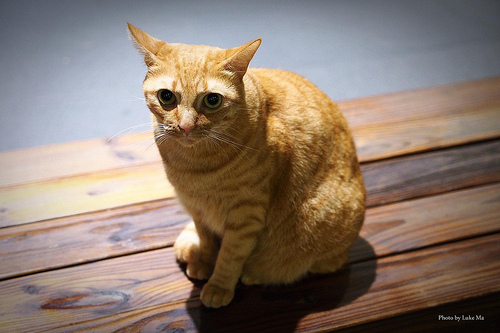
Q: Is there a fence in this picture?
A: No, there are no fences.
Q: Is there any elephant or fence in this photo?
A: No, there are no fences or elephants.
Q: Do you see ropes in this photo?
A: No, there are no ropes.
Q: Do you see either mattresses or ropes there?
A: No, there are no ropes or mattresses.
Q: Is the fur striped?
A: Yes, the fur is striped.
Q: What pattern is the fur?
A: The fur is striped.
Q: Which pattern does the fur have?
A: The fur has striped pattern.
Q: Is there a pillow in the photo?
A: No, there are no pillows.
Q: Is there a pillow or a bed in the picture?
A: No, there are no pillows or beds.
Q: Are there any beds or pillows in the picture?
A: No, there are no pillows or beds.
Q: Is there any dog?
A: No, there are no dogs.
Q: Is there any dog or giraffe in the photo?
A: No, there are no dogs or giraffes.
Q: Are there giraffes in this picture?
A: No, there are no giraffes.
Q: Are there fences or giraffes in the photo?
A: No, there are no giraffes or fences.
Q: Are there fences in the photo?
A: No, there are no fences.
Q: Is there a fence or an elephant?
A: No, there are no fences or elephants.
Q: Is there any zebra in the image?
A: No, there are no zebras.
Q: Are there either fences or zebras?
A: No, there are no zebras or fences.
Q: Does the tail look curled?
A: Yes, the tail is curled.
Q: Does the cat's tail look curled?
A: Yes, the tail is curled.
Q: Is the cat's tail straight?
A: No, the tail is curled.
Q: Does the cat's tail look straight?
A: No, the tail is curled.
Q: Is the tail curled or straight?
A: The tail is curled.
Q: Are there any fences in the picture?
A: No, there are no fences.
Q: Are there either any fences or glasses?
A: No, there are no fences or glasses.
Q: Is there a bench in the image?
A: Yes, there is a bench.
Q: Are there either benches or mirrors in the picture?
A: Yes, there is a bench.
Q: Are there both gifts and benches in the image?
A: No, there is a bench but no gifts.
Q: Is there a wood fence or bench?
A: Yes, there is a wood bench.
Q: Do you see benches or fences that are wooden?
A: Yes, the bench is wooden.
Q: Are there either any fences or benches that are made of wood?
A: Yes, the bench is made of wood.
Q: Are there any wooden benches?
A: Yes, there is a wood bench.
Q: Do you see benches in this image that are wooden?
A: Yes, there is a bench that is wooden.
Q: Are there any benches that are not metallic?
A: Yes, there is a wooden bench.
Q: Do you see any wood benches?
A: Yes, there is a bench that is made of wood.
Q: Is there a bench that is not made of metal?
A: Yes, there is a bench that is made of wood.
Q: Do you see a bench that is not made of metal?
A: Yes, there is a bench that is made of wood.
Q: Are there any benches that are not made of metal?
A: Yes, there is a bench that is made of wood.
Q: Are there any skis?
A: No, there are no skis.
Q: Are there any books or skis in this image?
A: No, there are no skis or books.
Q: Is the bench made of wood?
A: Yes, the bench is made of wood.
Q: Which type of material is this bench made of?
A: The bench is made of wood.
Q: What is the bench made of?
A: The bench is made of wood.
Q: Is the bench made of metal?
A: No, the bench is made of wood.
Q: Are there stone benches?
A: No, there is a bench but it is made of wood.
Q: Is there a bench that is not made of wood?
A: No, there is a bench but it is made of wood.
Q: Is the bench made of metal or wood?
A: The bench is made of wood.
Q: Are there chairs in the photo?
A: No, there are no chairs.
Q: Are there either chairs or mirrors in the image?
A: No, there are no chairs or mirrors.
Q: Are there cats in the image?
A: Yes, there is a cat.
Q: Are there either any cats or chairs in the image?
A: Yes, there is a cat.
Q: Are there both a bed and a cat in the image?
A: No, there is a cat but no beds.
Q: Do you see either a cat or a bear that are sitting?
A: Yes, the cat is sitting.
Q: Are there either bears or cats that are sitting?
A: Yes, the cat is sitting.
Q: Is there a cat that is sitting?
A: Yes, there is a cat that is sitting.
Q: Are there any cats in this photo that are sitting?
A: Yes, there is a cat that is sitting.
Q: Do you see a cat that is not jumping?
A: Yes, there is a cat that is sitting .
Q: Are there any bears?
A: No, there are no bears.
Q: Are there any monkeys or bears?
A: No, there are no bears or monkeys.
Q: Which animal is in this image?
A: The animal is a cat.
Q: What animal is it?
A: The animal is a cat.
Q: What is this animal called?
A: This is a cat.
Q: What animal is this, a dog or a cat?
A: This is a cat.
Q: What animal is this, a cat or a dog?
A: This is a cat.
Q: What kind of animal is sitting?
A: The animal is a cat.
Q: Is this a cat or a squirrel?
A: This is a cat.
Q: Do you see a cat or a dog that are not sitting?
A: No, there is a cat but it is sitting.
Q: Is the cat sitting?
A: Yes, the cat is sitting.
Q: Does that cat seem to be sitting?
A: Yes, the cat is sitting.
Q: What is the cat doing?
A: The cat is sitting.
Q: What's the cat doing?
A: The cat is sitting.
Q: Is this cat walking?
A: No, the cat is sitting.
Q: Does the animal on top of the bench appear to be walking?
A: No, the cat is sitting.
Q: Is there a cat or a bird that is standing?
A: No, there is a cat but it is sitting.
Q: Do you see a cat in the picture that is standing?
A: No, there is a cat but it is sitting.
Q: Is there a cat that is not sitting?
A: No, there is a cat but it is sitting.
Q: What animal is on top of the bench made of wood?
A: The cat is on top of the bench.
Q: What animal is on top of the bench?
A: The cat is on top of the bench.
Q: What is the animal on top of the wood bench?
A: The animal is a cat.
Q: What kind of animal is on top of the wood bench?
A: The animal is a cat.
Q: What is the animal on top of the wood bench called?
A: The animal is a cat.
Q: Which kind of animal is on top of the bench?
A: The animal is a cat.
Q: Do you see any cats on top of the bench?
A: Yes, there is a cat on top of the bench.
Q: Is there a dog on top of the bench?
A: No, there is a cat on top of the bench.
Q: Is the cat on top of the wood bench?
A: Yes, the cat is on top of the bench.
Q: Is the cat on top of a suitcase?
A: No, the cat is on top of the bench.